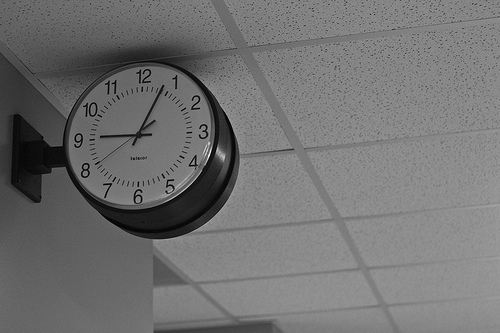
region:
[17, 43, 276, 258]
black clock hanging on wall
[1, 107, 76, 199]
metal support connecting clock to wall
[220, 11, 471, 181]
ceiling tiles covered with specks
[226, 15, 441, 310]
metal frame supporting ceiling tiles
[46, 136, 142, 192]
hand marking time in seconds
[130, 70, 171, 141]
hand marking time in minutes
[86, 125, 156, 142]
hand marking time in hours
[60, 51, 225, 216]
numbers around the edge of clock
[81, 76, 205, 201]
circle of lines with every fifth line in bold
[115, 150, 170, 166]
clock manufacturer printed on clock face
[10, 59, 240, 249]
Clock is mounted to wall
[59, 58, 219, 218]
Clock is analog style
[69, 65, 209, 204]
Clock face is white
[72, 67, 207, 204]
Clock markings are black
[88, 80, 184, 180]
Clock has three hands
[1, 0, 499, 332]
Ceiling is false hung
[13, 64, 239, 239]
Clock is covered in black metal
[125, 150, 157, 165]
Clock has writing on the face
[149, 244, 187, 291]
Lights are hung in the ceiling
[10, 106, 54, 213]
Four screws hold metal to wall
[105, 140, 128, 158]
part of a second hand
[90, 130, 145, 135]
ahour hand of a clock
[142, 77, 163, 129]
a minute hand of a clock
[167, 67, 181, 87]
number one symbol of a clock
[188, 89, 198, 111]
number two symbol of clock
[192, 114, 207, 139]
number three symbol of a clock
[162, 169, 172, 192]
number five symbol of a clock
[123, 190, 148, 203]
number six symbol of a clock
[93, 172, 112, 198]
number seven symbol of a clock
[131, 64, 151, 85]
number twelve symbol of a clock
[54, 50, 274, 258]
Clock on the wall.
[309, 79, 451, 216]
Drop ceiling tile.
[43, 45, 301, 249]
Office wall clock.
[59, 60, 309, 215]
After nine o'clock on the clock.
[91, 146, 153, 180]
Second hand on the clock.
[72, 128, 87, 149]
Number 9 on the clock.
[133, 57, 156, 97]
12 on the clock.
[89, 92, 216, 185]
Hands of the clock.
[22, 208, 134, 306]
Office wall.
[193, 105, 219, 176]
Number three on the clock.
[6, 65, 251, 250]
A clock on the wall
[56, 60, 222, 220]
A face of a clock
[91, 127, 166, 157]
An hour hand on a clock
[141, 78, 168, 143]
A minute hand on a clock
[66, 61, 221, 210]
The clock reads 9:04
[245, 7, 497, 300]
Ceiling tiles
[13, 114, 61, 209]
A black wall mount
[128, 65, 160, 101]
Number 12 on the clock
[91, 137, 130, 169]
Seconds hand on a clock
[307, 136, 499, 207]
A rectangle wall tile